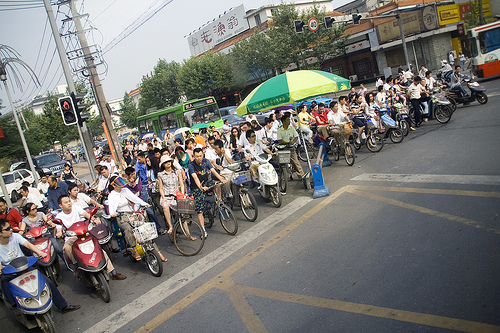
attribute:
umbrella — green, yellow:
[232, 65, 355, 118]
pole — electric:
[64, 1, 128, 172]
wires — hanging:
[1, 42, 44, 93]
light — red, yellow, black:
[57, 93, 78, 127]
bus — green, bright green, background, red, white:
[130, 93, 228, 140]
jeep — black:
[23, 152, 73, 182]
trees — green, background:
[177, 47, 245, 111]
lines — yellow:
[129, 182, 499, 331]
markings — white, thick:
[349, 163, 500, 193]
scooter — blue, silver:
[2, 252, 62, 332]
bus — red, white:
[463, 16, 500, 84]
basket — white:
[128, 220, 158, 244]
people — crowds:
[2, 56, 465, 332]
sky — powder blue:
[1, 1, 325, 116]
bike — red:
[44, 206, 115, 304]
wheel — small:
[28, 304, 55, 333]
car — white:
[2, 165, 43, 209]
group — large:
[4, 60, 456, 319]